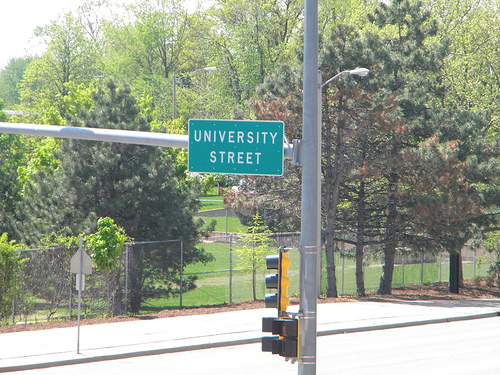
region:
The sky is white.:
[1, 0, 305, 76]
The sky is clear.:
[0, 0, 307, 75]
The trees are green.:
[1, 2, 498, 321]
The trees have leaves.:
[0, 0, 499, 326]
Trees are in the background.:
[0, 0, 499, 328]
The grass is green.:
[1, 183, 498, 327]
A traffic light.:
[261, 245, 290, 316]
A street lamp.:
[314, 66, 374, 371]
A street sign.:
[186, 115, 285, 177]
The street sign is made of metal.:
[185, 116, 285, 178]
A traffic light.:
[259, 246, 302, 363]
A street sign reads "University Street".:
[185, 118, 285, 177]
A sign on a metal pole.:
[68, 239, 90, 356]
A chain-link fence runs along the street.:
[3, 232, 498, 332]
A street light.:
[317, 62, 369, 92]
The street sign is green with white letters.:
[185, 116, 285, 177]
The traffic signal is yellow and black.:
[261, 247, 311, 363]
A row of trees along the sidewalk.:
[317, 44, 499, 304]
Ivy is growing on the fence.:
[2, 213, 129, 327]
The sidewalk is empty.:
[1, 281, 497, 373]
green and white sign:
[186, 106, 318, 197]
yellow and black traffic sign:
[263, 247, 308, 313]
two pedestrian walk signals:
[269, 313, 303, 358]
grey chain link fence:
[54, 225, 321, 315]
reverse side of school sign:
[65, 243, 88, 346]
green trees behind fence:
[14, 82, 205, 317]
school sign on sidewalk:
[51, 290, 284, 358]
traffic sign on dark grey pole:
[303, 45, 335, 374]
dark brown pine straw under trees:
[35, 285, 277, 337]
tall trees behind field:
[8, 36, 490, 277]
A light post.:
[312, 65, 374, 374]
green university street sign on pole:
[189, 121, 299, 173]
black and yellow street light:
[265, 248, 290, 312]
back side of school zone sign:
[71, 242, 93, 274]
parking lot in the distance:
[204, 203, 238, 220]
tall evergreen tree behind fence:
[28, 87, 197, 310]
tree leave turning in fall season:
[407, 137, 464, 231]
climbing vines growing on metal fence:
[82, 218, 135, 270]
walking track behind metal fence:
[352, 261, 390, 271]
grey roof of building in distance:
[0, 106, 42, 118]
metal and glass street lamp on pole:
[318, 65, 370, 97]